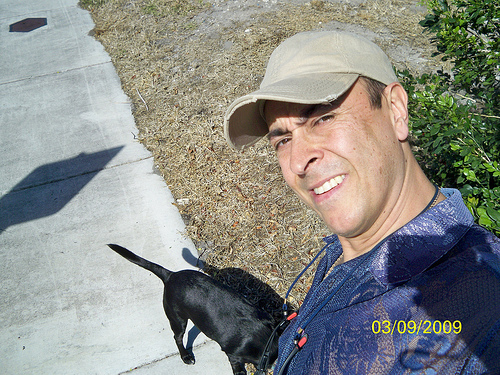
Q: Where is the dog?
A: Standing on sidewalk.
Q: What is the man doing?
A: Looking at the camera.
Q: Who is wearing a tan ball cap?
A: The man.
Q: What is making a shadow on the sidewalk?
A: A sign.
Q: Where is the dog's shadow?
A: On the grass.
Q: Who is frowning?
A: A man.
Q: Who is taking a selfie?
A: A man.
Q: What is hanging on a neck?
A: Sunglasses.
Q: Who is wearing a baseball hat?
A: A man.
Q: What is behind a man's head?
A: A bush.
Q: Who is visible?
A: A man.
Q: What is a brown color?
A: The grass.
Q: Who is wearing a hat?
A: A man.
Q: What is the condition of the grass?
A: The grass is dead.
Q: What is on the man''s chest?
A: A blue coat.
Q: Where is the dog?
A: At the man's feet.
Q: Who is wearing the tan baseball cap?
A: The man.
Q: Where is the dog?
A: On the sidewalk.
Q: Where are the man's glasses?
A: Around his neck on a string.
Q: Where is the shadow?
A: On the sidewalk.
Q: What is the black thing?
A: The dog.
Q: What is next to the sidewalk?
A: Dead grass.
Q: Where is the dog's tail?
A: Behind it.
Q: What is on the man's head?
A: A hat.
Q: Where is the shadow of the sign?
A: On the sidewalk.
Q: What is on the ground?
A: Dog.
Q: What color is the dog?
A: Black.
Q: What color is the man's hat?
A: Gray.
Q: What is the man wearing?
A: Jacket.